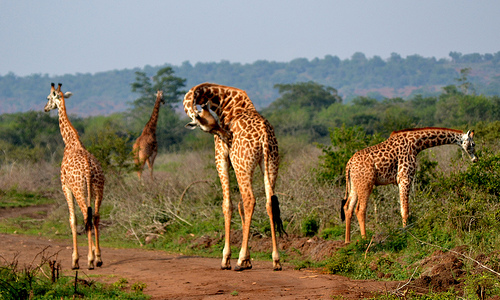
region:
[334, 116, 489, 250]
giraffe is eating grass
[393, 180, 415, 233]
front legs of giraffe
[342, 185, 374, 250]
back legs of giraffe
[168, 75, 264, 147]
neck of giraffe is back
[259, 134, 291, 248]
long tail of giraffe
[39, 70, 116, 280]
the giraffe is in motion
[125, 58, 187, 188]
a giraffe in front a tree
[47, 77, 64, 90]
giraffe has two horns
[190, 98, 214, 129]
giraffe has two horns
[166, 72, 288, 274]
a giraffe licking the back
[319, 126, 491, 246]
a giraffe eating leaves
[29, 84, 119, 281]
a giraffe trotting on a dirt road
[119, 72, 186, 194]
a giraffe looking in the distance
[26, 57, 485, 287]
giraffes in an African sevana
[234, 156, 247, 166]
brown spot white giraffe fur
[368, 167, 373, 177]
brown spot white giraffe fur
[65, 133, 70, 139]
brown spot white giraffe fur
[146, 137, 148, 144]
brown spot white giraffe fur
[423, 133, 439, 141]
brown spot white giraffe fur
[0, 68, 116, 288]
this is a girraffe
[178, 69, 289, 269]
this is a girraffe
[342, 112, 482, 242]
this is a girraffe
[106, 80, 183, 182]
this is a girraffe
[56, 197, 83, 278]
this is a leg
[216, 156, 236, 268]
this is a leg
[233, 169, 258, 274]
this is a leg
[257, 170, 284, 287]
this is a leg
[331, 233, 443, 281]
this is a green vegetation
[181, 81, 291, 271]
A giraffe cleaning itself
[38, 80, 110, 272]
a giraffe walking down a dirt path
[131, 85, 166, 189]
a giraffe walking down a dirt path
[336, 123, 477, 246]
a giraffe eating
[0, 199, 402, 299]
A small dirt path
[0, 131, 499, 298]
A grassy landscape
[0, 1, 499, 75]
A clear blue sky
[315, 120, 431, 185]
A large full bush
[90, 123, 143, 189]
A large full bush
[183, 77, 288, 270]
Giraffe bending its neck.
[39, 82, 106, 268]
Young giraffe walking on dirt.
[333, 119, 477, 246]
Young giraffe eating some grass.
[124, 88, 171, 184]
Adult giraffe in the distance.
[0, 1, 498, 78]
Blue sky with no clouds.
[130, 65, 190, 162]
Large tree on the savannah.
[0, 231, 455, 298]
Dirt trail with two giraffes walking on it.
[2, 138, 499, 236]
Tall grey colored grass.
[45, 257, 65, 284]
Small twig in the grass.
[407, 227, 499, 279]
Long stick next to clump of dirt.